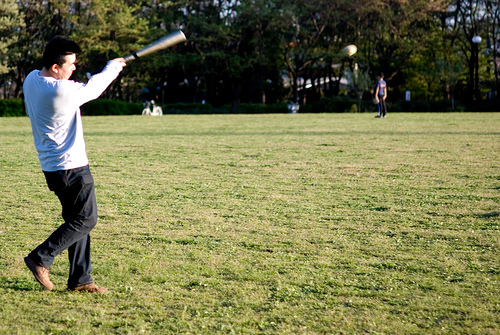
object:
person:
[13, 33, 131, 298]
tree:
[191, 0, 226, 113]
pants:
[31, 170, 124, 281]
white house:
[283, 70, 355, 113]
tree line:
[0, 3, 146, 114]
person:
[370, 69, 395, 120]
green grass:
[1, 111, 27, 199]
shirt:
[19, 55, 144, 179]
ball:
[344, 45, 356, 55]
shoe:
[23, 252, 54, 291]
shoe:
[69, 282, 106, 294]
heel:
[20, 255, 33, 267]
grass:
[135, 262, 173, 318]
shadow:
[467, 208, 497, 220]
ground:
[317, 114, 497, 143]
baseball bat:
[121, 31, 187, 67]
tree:
[385, 0, 414, 112]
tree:
[269, 0, 328, 119]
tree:
[383, 1, 409, 109]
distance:
[415, 17, 459, 109]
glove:
[372, 98, 382, 104]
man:
[17, 33, 129, 296]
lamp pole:
[466, 31, 483, 110]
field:
[418, 101, 500, 333]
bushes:
[189, 81, 232, 112]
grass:
[404, 176, 488, 315]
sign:
[401, 86, 415, 99]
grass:
[287, 264, 316, 301]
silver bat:
[123, 30, 185, 65]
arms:
[374, 84, 382, 96]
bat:
[115, 25, 191, 60]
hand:
[109, 52, 132, 69]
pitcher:
[373, 72, 388, 116]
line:
[258, 92, 319, 120]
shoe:
[15, 245, 75, 302]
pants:
[24, 161, 96, 282]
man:
[373, 73, 388, 119]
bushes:
[465, 85, 494, 112]